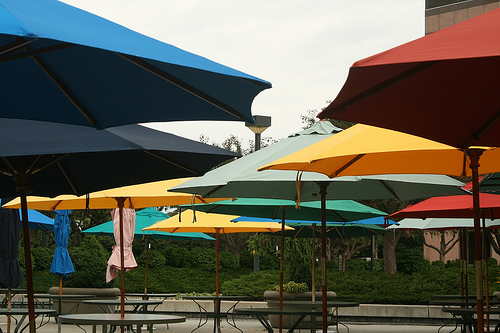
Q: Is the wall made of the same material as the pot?
A: Yes, both the wall and the pot are made of concrete.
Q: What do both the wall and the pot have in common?
A: The material, both the wall and the pot are concrete.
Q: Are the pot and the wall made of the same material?
A: Yes, both the pot and the wall are made of concrete.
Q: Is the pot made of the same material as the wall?
A: Yes, both the pot and the wall are made of concrete.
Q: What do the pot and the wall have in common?
A: The material, both the pot and the wall are concrete.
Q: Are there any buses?
A: No, there are no buses.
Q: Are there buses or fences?
A: No, there are no buses or fences.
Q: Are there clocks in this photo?
A: No, there are no clocks.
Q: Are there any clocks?
A: No, there are no clocks.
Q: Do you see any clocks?
A: No, there are no clocks.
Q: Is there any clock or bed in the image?
A: No, there are no clocks or beds.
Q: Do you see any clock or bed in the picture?
A: No, there are no clocks or beds.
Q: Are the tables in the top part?
A: No, the tables are in the bottom of the image.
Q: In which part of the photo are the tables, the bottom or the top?
A: The tables are in the bottom of the image.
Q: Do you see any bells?
A: No, there are no bells.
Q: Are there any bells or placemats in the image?
A: No, there are no bells or placemats.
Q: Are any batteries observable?
A: No, there are no batteries.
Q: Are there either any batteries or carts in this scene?
A: No, there are no batteries or carts.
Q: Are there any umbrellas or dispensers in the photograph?
A: Yes, there is an umbrella.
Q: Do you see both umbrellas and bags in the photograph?
A: No, there is an umbrella but no bags.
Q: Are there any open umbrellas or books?
A: Yes, there is an open umbrella.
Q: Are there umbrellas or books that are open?
A: Yes, the umbrella is open.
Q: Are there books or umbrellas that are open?
A: Yes, the umbrella is open.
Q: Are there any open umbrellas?
A: Yes, there is an open umbrella.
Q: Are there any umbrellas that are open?
A: Yes, there is an umbrella that is open.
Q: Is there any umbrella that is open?
A: Yes, there is an umbrella that is open.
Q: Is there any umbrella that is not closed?
A: Yes, there is a open umbrella.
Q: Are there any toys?
A: No, there are no toys.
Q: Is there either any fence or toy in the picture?
A: No, there are no toys or fences.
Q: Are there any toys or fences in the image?
A: No, there are no toys or fences.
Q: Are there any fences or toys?
A: No, there are no toys or fences.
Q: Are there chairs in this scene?
A: No, there are no chairs.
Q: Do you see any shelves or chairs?
A: No, there are no chairs or shelves.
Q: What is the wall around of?
A: The wall is around the patio.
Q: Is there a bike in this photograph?
A: No, there are no bikes.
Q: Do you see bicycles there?
A: No, there are no bicycles.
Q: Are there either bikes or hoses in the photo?
A: No, there are no bikes or hoses.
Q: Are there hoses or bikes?
A: No, there are no bikes or hoses.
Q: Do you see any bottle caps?
A: No, there are no bottle caps.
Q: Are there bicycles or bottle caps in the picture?
A: No, there are no bottle caps or bicycles.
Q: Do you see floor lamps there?
A: No, there are no floor lamps.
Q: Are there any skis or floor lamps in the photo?
A: No, there are no floor lamps or skis.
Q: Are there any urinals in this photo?
A: No, there are no urinals.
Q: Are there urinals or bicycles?
A: No, there are no urinals or bicycles.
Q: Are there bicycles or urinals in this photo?
A: No, there are no urinals or bicycles.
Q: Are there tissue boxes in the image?
A: No, there are no tissue boxes.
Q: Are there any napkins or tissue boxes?
A: No, there are no tissue boxes or napkins.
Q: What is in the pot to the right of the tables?
A: The bushes are in the pot.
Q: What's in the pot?
A: The bushes are in the pot.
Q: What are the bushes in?
A: The bushes are in the pot.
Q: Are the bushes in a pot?
A: Yes, the bushes are in a pot.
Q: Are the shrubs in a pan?
A: No, the shrubs are in a pot.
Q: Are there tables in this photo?
A: Yes, there is a table.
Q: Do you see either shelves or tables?
A: Yes, there is a table.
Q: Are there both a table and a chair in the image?
A: No, there is a table but no chairs.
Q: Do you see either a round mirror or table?
A: Yes, there is a round table.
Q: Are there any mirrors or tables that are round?
A: Yes, the table is round.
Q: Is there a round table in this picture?
A: Yes, there is a round table.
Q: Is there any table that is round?
A: Yes, there is a table that is round.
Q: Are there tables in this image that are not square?
A: Yes, there is a round table.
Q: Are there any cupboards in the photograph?
A: No, there are no cupboards.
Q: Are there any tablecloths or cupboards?
A: No, there are no cupboards or tablecloths.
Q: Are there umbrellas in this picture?
A: Yes, there are umbrellas.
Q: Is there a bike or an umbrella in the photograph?
A: Yes, there are umbrellas.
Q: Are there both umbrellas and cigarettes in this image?
A: No, there are umbrellas but no cigarettes.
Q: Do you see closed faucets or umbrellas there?
A: Yes, there are closed umbrellas.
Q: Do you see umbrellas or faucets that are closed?
A: Yes, the umbrellas are closed.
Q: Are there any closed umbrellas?
A: Yes, there are closed umbrellas.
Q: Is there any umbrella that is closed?
A: Yes, there are umbrellas that are closed.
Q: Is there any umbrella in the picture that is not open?
A: Yes, there are closed umbrellas.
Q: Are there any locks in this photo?
A: No, there are no locks.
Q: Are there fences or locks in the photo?
A: No, there are no locks or fences.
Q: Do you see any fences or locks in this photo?
A: No, there are no locks or fences.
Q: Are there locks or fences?
A: No, there are no locks or fences.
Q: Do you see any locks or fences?
A: No, there are no locks or fences.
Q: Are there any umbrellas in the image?
A: Yes, there are umbrellas.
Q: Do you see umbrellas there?
A: Yes, there are umbrellas.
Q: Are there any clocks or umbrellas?
A: Yes, there are umbrellas.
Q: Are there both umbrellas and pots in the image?
A: Yes, there are both umbrellas and a pot.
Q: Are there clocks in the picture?
A: No, there are no clocks.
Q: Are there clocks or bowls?
A: No, there are no clocks or bowls.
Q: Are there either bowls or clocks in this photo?
A: No, there are no clocks or bowls.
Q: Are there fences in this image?
A: No, there are no fences.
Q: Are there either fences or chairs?
A: No, there are no fences or chairs.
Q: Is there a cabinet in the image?
A: No, there are no cabinets.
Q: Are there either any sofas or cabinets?
A: No, there are no cabinets or sofas.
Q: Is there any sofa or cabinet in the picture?
A: No, there are no cabinets or sofas.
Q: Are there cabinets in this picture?
A: No, there are no cabinets.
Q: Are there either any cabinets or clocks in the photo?
A: No, there are no cabinets or clocks.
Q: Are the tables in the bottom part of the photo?
A: Yes, the tables are in the bottom of the image.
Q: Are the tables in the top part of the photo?
A: No, the tables are in the bottom of the image.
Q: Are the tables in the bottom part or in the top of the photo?
A: The tables are in the bottom of the image.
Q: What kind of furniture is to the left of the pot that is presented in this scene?
A: The pieces of furniture are tables.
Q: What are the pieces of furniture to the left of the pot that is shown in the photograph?
A: The pieces of furniture are tables.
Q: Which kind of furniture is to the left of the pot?
A: The pieces of furniture are tables.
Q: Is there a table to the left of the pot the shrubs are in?
A: Yes, there are tables to the left of the pot.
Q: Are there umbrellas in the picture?
A: Yes, there is an umbrella.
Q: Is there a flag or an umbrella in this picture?
A: Yes, there is an umbrella.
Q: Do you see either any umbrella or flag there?
A: Yes, there is an umbrella.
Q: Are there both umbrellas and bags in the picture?
A: No, there is an umbrella but no bags.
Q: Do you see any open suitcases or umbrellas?
A: Yes, there is an open umbrella.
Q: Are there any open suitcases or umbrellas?
A: Yes, there is an open umbrella.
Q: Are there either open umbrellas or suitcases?
A: Yes, there is an open umbrella.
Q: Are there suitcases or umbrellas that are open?
A: Yes, the umbrella is open.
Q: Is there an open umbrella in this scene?
A: Yes, there is an open umbrella.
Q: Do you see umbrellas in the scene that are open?
A: Yes, there is an umbrella that is open.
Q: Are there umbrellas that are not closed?
A: Yes, there is a open umbrella.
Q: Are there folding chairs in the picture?
A: No, there are no folding chairs.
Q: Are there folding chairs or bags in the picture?
A: No, there are no folding chairs or bags.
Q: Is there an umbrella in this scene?
A: Yes, there is an umbrella.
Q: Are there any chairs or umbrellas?
A: Yes, there is an umbrella.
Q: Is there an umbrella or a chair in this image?
A: Yes, there is an umbrella.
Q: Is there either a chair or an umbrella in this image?
A: Yes, there is an umbrella.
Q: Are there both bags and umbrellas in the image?
A: No, there is an umbrella but no bags.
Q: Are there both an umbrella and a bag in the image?
A: No, there is an umbrella but no bags.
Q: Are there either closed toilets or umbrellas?
A: Yes, there is a closed umbrella.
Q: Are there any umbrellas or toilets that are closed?
A: Yes, the umbrella is closed.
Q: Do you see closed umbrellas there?
A: Yes, there is a closed umbrella.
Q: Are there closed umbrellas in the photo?
A: Yes, there is a closed umbrella.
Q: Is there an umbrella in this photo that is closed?
A: Yes, there is an umbrella that is closed.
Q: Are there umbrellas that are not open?
A: Yes, there is an closed umbrella.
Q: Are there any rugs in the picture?
A: No, there are no rugs.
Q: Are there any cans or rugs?
A: No, there are no rugs or cans.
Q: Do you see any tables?
A: Yes, there is a table.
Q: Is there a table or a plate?
A: Yes, there is a table.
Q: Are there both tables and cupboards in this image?
A: No, there is a table but no cupboards.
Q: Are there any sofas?
A: No, there are no sofas.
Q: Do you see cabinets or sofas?
A: No, there are no sofas or cabinets.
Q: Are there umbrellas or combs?
A: Yes, there is an umbrella.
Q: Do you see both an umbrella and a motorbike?
A: No, there is an umbrella but no motorcycles.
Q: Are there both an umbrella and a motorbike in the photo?
A: No, there is an umbrella but no motorcycles.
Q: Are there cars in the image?
A: No, there are no cars.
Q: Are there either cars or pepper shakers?
A: No, there are no cars or pepper shakers.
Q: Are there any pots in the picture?
A: Yes, there is a pot.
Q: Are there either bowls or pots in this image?
A: Yes, there is a pot.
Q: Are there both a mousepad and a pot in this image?
A: No, there is a pot but no mouse pads.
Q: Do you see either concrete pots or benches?
A: Yes, there is a concrete pot.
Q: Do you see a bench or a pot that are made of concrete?
A: Yes, the pot is made of concrete.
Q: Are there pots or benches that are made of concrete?
A: Yes, the pot is made of concrete.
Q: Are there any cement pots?
A: Yes, there is a pot that is made of cement.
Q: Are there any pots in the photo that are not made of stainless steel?
A: Yes, there is a pot that is made of concrete.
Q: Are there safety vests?
A: No, there are no safety vests.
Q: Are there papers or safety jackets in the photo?
A: No, there are no safety jackets or papers.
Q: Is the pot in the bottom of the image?
A: Yes, the pot is in the bottom of the image.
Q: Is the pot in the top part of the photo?
A: No, the pot is in the bottom of the image.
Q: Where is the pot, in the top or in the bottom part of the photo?
A: The pot is in the bottom of the image.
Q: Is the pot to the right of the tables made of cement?
A: Yes, the pot is made of cement.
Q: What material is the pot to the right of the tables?
A: The pot is made of concrete.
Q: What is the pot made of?
A: The pot is made of concrete.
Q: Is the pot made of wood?
A: No, the pot is made of concrete.